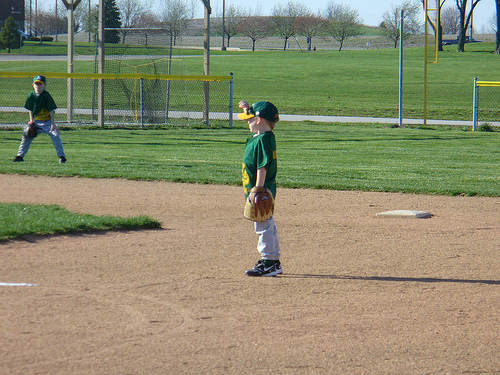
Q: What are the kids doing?
A: Baseball.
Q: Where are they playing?
A: Baseball diamond.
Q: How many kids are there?
A: Two.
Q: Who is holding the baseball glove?
A: Player.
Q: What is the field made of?
A: Grass.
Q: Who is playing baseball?
A: Kids.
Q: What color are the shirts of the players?
A: Green.